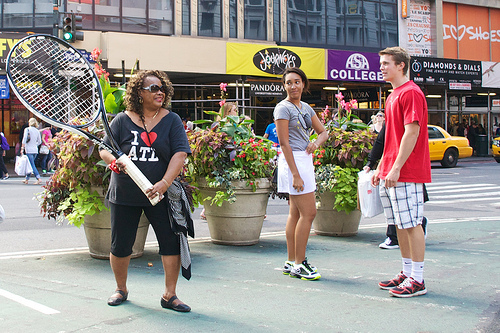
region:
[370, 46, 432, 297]
Man wearing red shirt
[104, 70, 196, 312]
Woman carrying huge racket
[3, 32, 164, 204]
Racket is huge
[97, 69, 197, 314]
Woman wearing I heart ATL shirt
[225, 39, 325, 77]
Journeys banner is yellow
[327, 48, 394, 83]
ASA College banner is purple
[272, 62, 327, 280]
Woman wearing white skirt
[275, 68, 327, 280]
Woman in white skirt looking at woman holding racket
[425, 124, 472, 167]
Cab is yellow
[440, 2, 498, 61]
I heart SHOES banner is orange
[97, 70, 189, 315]
Woman holding huge tennis racket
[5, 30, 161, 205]
Huge tennis racket held by woman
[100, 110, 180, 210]
I heart ATL black shirt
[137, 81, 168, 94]
Sunglasses on woman holding huge tennis racket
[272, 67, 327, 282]
Young lady observing woman that has huge tennis racket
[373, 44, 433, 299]
Young man sees woman with huge tennis racket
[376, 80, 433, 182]
Red shirt worn by young man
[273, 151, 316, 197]
White skirt on young woman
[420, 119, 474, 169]
Yellow taxicab in background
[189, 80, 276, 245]
Large pot of flowers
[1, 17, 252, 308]
woman holding large tennis racket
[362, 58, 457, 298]
man in red shirt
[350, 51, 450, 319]
man in plaid shorts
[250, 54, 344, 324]
woman in white skirt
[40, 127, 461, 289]
three large flower pots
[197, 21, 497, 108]
three signs on buildings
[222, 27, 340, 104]
yellow sign with black circle and white writing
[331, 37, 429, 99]
purple sign with white writing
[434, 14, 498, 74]
pink sign with i love shoes in white lettering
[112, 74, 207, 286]
woman wearing black shirt with i love atl on it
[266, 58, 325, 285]
a person in the street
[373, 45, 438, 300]
a person in the street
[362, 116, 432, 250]
a person in the street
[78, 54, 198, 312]
a person in the street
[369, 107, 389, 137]
a person in the street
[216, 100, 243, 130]
a person in the street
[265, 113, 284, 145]
a person in the street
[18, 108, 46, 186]
a person in the street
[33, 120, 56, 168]
a person in the street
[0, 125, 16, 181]
a person in the street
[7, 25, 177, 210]
The woman is holding a racket.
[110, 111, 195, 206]
The woman's shirt is black.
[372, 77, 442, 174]
The man's shirt is red.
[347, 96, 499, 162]
Taxi's parked on the side of the road.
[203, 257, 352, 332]
The ground is grey.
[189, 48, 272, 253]
Potted plants between the people and street.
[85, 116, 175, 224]
The handle of the racket is white.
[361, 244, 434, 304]
The man's shoes are red.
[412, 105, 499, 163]
The taxi's are yellow.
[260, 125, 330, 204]
The girls skirt is white.